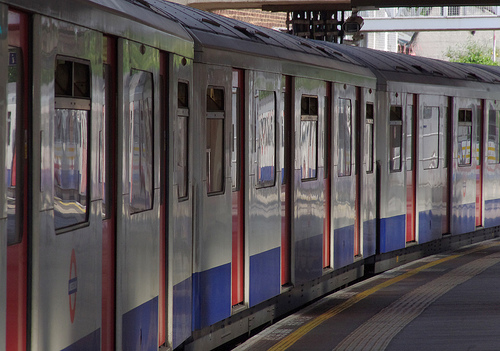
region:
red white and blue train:
[45, 84, 499, 328]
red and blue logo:
[53, 251, 89, 331]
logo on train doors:
[53, 240, 90, 332]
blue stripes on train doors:
[90, 207, 498, 332]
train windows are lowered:
[53, 57, 83, 129]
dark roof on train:
[139, 35, 487, 105]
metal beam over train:
[342, 9, 498, 51]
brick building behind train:
[167, 0, 315, 47]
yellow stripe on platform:
[288, 215, 483, 342]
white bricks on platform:
[342, 249, 494, 346]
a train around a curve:
[54, 18, 486, 350]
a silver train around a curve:
[30, 9, 465, 349]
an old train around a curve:
[19, 18, 496, 328]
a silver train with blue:
[22, 2, 489, 296]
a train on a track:
[32, 5, 494, 314]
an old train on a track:
[37, 7, 497, 315]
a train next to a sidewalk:
[47, 7, 499, 339]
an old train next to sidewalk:
[54, 6, 496, 343]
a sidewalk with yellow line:
[184, 208, 485, 349]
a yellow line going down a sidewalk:
[255, 193, 490, 349]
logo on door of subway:
[66, 243, 86, 320]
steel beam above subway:
[376, 13, 498, 43]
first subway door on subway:
[32, 38, 97, 350]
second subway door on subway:
[125, 53, 171, 342]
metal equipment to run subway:
[283, 9, 367, 37]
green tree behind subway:
[445, 35, 496, 65]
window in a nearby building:
[446, 5, 461, 15]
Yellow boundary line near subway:
[272, 277, 389, 342]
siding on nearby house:
[424, 38, 458, 62]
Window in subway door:
[337, 97, 358, 179]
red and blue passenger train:
[3, 3, 498, 345]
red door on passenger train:
[1, 2, 30, 349]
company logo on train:
[58, 244, 84, 329]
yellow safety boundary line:
[262, 235, 498, 349]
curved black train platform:
[224, 225, 499, 349]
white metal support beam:
[283, 9, 498, 36]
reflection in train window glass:
[251, 84, 281, 192]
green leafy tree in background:
[437, 35, 499, 66]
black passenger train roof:
[119, 0, 499, 90]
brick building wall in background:
[222, 7, 318, 34]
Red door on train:
[100, 33, 117, 350]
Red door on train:
[158, 48, 168, 349]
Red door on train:
[231, 70, 245, 307]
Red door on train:
[277, 73, 292, 285]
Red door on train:
[321, 78, 332, 268]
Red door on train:
[352, 87, 362, 256]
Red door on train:
[405, 91, 418, 241]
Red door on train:
[440, 92, 447, 232]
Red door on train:
[475, 98, 482, 227]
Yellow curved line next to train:
[267, 239, 497, 349]